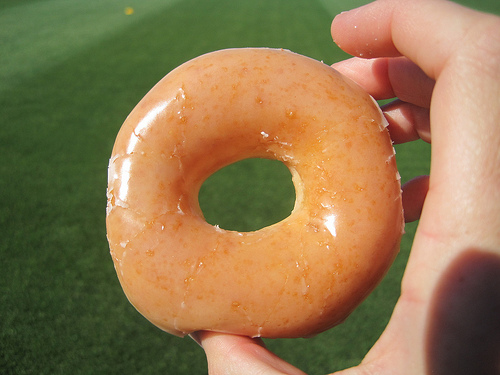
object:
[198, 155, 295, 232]
hole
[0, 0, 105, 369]
grass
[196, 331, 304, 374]
finger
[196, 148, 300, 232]
hole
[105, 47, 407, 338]
cow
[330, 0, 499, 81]
finger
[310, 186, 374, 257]
sugar coating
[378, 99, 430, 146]
finger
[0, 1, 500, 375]
vegetation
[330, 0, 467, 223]
four fingers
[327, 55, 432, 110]
finger